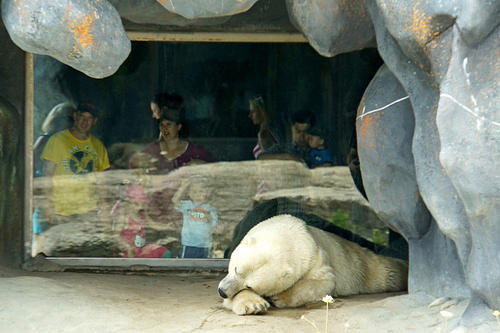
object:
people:
[249, 95, 288, 160]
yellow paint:
[381, 0, 452, 88]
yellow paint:
[51, 0, 120, 74]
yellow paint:
[355, 97, 399, 174]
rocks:
[354, 0, 499, 328]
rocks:
[113, 0, 379, 58]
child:
[110, 184, 171, 258]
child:
[171, 174, 219, 258]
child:
[308, 125, 334, 169]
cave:
[0, 0, 500, 333]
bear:
[217, 213, 409, 316]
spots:
[57, 6, 102, 58]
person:
[129, 109, 219, 239]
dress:
[113, 210, 167, 258]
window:
[33, 40, 390, 259]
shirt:
[128, 139, 218, 223]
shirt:
[40, 129, 111, 217]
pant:
[177, 245, 214, 258]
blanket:
[223, 196, 409, 260]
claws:
[245, 302, 267, 311]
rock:
[2, 0, 132, 79]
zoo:
[0, 0, 500, 333]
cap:
[125, 185, 150, 204]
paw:
[231, 290, 272, 316]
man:
[39, 106, 110, 233]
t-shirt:
[39, 129, 111, 217]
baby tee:
[174, 199, 219, 248]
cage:
[0, 0, 500, 333]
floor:
[0, 271, 500, 333]